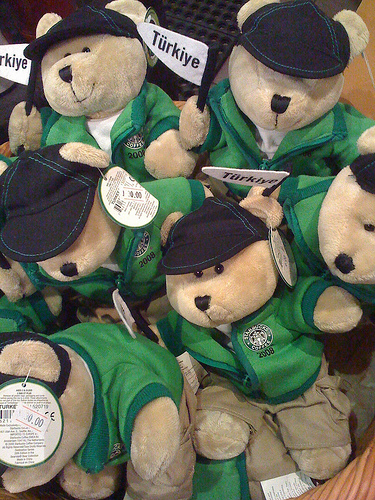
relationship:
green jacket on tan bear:
[154, 272, 338, 405] [139, 196, 363, 480]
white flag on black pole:
[135, 11, 225, 90] [209, 39, 231, 115]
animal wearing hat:
[155, 191, 365, 482] [158, 195, 269, 275]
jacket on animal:
[176, 287, 330, 406] [202, 5, 372, 172]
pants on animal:
[195, 366, 353, 449] [155, 191, 365, 482]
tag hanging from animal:
[267, 223, 299, 289] [155, 191, 365, 482]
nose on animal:
[186, 291, 216, 314] [142, 205, 347, 456]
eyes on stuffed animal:
[212, 262, 227, 272] [137, 185, 346, 495]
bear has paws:
[179, 2, 374, 176] [175, 92, 211, 149]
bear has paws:
[0, 5, 145, 168] [139, 136, 197, 176]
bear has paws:
[163, 199, 365, 337] [7, 92, 43, 152]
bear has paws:
[163, 199, 365, 337] [313, 286, 364, 334]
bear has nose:
[179, 2, 374, 176] [268, 91, 294, 124]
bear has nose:
[0, 5, 145, 168] [53, 60, 81, 89]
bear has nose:
[1, 142, 205, 305] [329, 251, 360, 277]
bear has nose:
[277, 125, 373, 290] [58, 260, 82, 278]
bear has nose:
[153, 188, 363, 486] [188, 292, 213, 310]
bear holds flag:
[209, 4, 367, 166] [144, 24, 214, 82]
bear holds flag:
[35, 5, 185, 168] [144, 24, 214, 82]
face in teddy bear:
[170, 259, 271, 315] [147, 187, 319, 437]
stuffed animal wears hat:
[142, 182, 373, 499] [161, 191, 275, 272]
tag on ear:
[267, 223, 299, 289] [240, 195, 283, 228]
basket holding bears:
[290, 440, 372, 498] [12, 7, 357, 327]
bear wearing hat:
[149, 207, 369, 485] [168, 200, 274, 280]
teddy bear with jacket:
[181, 1, 372, 177] [200, 79, 368, 179]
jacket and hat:
[200, 79, 368, 179] [241, 9, 348, 79]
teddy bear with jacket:
[25, 0, 188, 177] [38, 103, 175, 146]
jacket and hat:
[38, 103, 175, 146] [23, 4, 139, 60]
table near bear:
[339, 0, 373, 124] [140, 2, 374, 175]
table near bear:
[339, 0, 373, 124] [146, 204, 357, 495]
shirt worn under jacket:
[137, 137, 321, 280] [36, 79, 183, 186]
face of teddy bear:
[239, 57, 340, 130] [181, 1, 372, 177]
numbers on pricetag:
[25, 413, 43, 426] [10, 398, 55, 431]